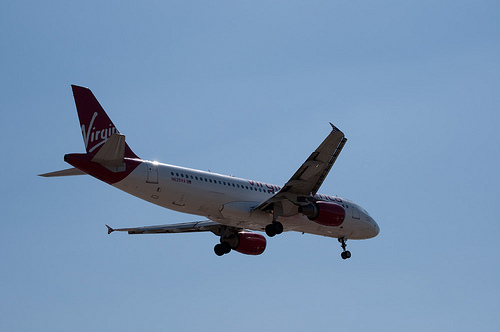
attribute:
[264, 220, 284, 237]
wheels — black, set, down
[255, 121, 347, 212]
wing — outstretched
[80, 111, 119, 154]
logo — virgin, white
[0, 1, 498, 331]
sky — blue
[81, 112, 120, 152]
text — white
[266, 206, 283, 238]
landing gear — landing gear